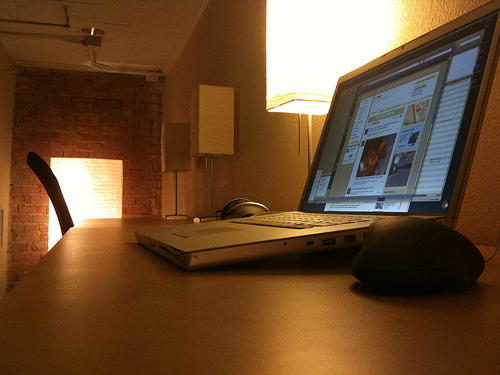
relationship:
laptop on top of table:
[132, 1, 499, 275] [2, 215, 499, 375]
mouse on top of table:
[343, 214, 487, 297] [2, 215, 499, 375]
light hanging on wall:
[261, 1, 383, 121] [161, 1, 499, 285]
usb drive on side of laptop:
[320, 232, 338, 248] [132, 1, 499, 275]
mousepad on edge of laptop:
[169, 222, 243, 240] [132, 1, 499, 275]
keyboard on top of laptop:
[232, 208, 373, 232] [132, 1, 499, 275]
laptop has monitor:
[132, 1, 499, 275] [297, 2, 498, 228]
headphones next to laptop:
[215, 196, 272, 221] [132, 1, 499, 275]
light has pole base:
[261, 1, 383, 121] [304, 112, 315, 181]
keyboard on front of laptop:
[232, 208, 373, 232] [132, 1, 499, 275]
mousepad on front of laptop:
[169, 222, 243, 240] [132, 1, 499, 275]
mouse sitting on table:
[343, 214, 487, 297] [2, 215, 499, 375]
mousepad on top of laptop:
[169, 222, 243, 240] [132, 1, 499, 275]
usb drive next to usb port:
[320, 232, 338, 248] [340, 230, 360, 245]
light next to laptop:
[261, 1, 383, 121] [132, 1, 499, 275]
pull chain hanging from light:
[292, 113, 305, 159] [261, 1, 383, 121]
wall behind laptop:
[161, 1, 499, 285] [132, 1, 499, 275]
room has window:
[1, 1, 500, 373] [48, 153, 125, 251]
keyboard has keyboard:
[232, 208, 373, 232] [231, 212, 383, 230]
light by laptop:
[261, 1, 383, 121] [132, 1, 499, 275]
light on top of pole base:
[261, 1, 383, 121] [304, 112, 315, 181]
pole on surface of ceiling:
[85, 42, 167, 73] [2, 3, 209, 86]